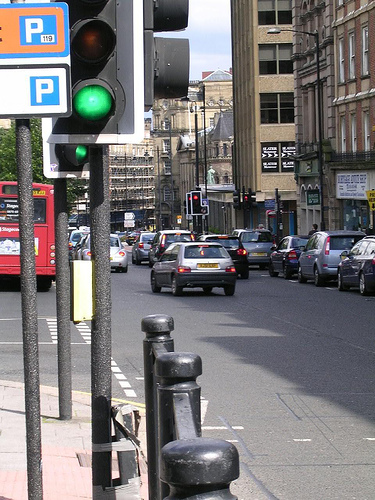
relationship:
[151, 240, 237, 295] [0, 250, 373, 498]
car going down street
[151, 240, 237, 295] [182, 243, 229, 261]
car has windshield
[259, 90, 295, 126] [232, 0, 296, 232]
window on side of building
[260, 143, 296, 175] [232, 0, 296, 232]
sign on front of building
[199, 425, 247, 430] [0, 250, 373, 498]
marking on top of street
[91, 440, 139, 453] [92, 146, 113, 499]
duct tape on top of pole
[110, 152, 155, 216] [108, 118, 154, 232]
scaffolding in front of building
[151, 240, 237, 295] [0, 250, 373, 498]
car driving on street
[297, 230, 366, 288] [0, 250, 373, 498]
car parked on street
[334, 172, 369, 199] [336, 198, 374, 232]
sign above store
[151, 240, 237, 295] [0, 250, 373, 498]
car driving down street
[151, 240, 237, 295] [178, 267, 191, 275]
car has light